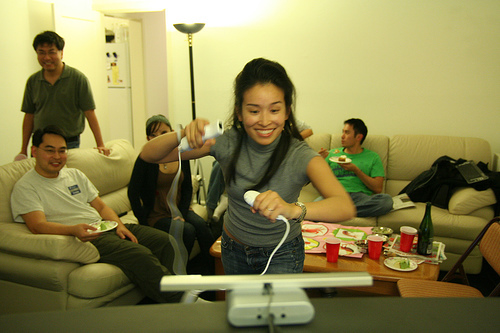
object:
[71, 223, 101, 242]
hand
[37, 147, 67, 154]
glasses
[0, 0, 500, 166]
wall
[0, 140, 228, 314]
love seat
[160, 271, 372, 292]
wii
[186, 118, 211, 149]
hand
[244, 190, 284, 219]
nunchuck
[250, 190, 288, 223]
hand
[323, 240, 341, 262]
cup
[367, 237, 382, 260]
cup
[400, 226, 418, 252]
cup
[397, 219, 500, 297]
chair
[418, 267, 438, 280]
corner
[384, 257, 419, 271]
utensil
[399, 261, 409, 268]
food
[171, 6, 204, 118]
lamp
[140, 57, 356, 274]
girl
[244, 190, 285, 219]
controller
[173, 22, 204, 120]
light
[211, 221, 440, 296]
coffee table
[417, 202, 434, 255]
bottle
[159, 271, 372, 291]
video game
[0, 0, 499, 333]
living room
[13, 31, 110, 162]
man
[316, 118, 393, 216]
man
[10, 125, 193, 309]
guy sitting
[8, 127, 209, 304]
guy wearing glasses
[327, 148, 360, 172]
guy holding a plate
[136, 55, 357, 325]
lady playing a game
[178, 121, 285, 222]
two controllers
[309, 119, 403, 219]
guy eating food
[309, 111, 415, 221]
guy holding plate up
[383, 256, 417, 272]
plate on table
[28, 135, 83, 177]
smiling man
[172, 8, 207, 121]
gold stand lamp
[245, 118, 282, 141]
big smile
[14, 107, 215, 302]
two people sitting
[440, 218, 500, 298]
striped metal chair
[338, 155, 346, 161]
plate of food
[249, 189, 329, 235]
hand with a ring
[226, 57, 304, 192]
dark long hair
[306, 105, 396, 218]
man eating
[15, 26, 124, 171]
man standing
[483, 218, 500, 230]
chair by the corner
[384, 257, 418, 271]
utensil with food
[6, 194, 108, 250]
hand resting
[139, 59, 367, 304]
girl playing a wii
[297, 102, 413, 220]
man sitting down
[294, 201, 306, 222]
wristwatch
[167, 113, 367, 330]
playing a video game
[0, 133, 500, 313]
couch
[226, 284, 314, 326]
camera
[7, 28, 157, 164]
behind the couch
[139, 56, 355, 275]
wiimote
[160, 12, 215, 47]
light behind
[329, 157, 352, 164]
plate